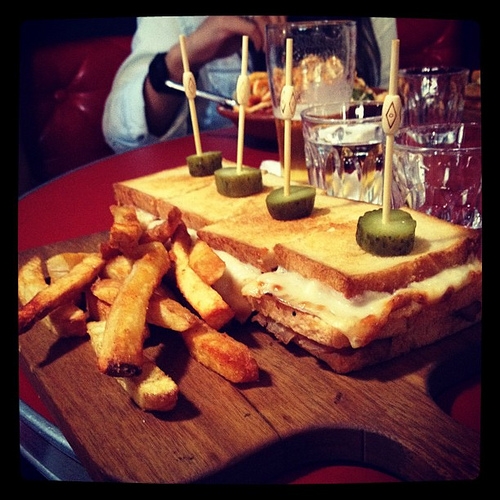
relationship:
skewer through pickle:
[378, 40, 401, 226] [355, 207, 420, 251]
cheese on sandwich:
[126, 143, 446, 377] [76, 180, 235, 454]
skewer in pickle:
[378, 40, 401, 226] [356, 205, 418, 256]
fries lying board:
[72, 226, 232, 396] [34, 236, 472, 485]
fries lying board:
[16, 198, 262, 414] [16, 226, 483, 486]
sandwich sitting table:
[262, 207, 481, 375] [13, 105, 498, 490]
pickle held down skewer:
[356, 205, 418, 256] [378, 40, 401, 226]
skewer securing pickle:
[378, 40, 401, 226] [356, 205, 418, 256]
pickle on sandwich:
[356, 205, 418, 256] [101, 139, 493, 381]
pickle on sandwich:
[265, 187, 316, 217] [101, 139, 493, 381]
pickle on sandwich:
[356, 205, 418, 256] [249, 200, 481, 362]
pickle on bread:
[356, 205, 418, 256] [156, 162, 288, 230]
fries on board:
[95, 247, 168, 373] [16, 226, 483, 486]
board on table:
[16, 226, 483, 486] [13, 105, 498, 490]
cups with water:
[299, 100, 400, 204] [314, 143, 360, 175]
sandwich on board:
[251, 204, 487, 378] [23, 261, 443, 438]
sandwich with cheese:
[101, 139, 493, 381] [224, 262, 379, 354]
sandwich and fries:
[151, 158, 411, 390] [38, 247, 250, 385]